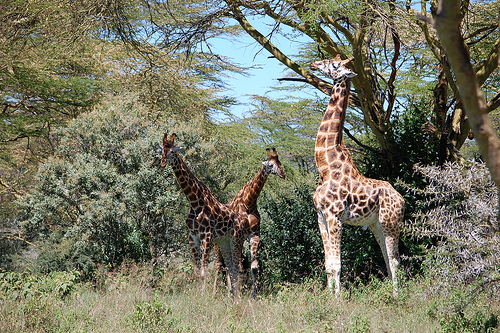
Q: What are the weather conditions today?
A: It is clear.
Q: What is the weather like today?
A: It is clear.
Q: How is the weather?
A: It is clear.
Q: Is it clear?
A: Yes, it is clear.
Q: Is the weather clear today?
A: Yes, it is clear.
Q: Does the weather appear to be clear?
A: Yes, it is clear.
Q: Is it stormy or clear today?
A: It is clear.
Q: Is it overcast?
A: No, it is clear.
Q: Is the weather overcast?
A: No, it is clear.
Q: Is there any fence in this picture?
A: No, there are no fences.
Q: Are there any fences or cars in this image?
A: No, there are no fences or cars.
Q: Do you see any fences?
A: No, there are no fences.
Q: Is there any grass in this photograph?
A: Yes, there is grass.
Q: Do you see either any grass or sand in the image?
A: Yes, there is grass.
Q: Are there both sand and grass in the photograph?
A: No, there is grass but no sand.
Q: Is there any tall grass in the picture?
A: Yes, there is tall grass.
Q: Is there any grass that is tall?
A: Yes, there is grass that is tall.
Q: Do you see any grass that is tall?
A: Yes, there is grass that is tall.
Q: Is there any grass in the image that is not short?
A: Yes, there is tall grass.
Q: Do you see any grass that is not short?
A: Yes, there is tall grass.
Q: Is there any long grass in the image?
A: Yes, there is long grass.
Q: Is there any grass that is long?
A: Yes, there is grass that is long.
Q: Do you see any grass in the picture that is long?
A: Yes, there is grass that is long.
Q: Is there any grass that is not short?
A: Yes, there is long grass.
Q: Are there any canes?
A: No, there are no canes.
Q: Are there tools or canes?
A: No, there are no canes or tools.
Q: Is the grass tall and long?
A: Yes, the grass is tall and long.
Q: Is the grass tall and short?
A: No, the grass is tall but long.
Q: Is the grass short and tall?
A: No, the grass is tall but long.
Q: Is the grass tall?
A: Yes, the grass is tall.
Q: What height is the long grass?
A: The grass is tall.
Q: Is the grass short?
A: No, the grass is tall.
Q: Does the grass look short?
A: No, the grass is tall.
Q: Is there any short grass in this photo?
A: No, there is grass but it is tall.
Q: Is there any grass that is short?
A: No, there is grass but it is tall.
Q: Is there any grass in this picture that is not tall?
A: No, there is grass but it is tall.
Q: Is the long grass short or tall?
A: The grass is tall.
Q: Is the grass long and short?
A: No, the grass is long but tall.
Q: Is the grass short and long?
A: No, the grass is long but tall.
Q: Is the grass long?
A: Yes, the grass is long.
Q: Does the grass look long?
A: Yes, the grass is long.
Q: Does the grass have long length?
A: Yes, the grass is long.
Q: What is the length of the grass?
A: The grass is long.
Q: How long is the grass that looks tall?
A: The grass is long.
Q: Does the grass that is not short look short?
A: No, the grass is long.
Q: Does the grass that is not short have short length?
A: No, the grass is long.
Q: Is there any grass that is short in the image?
A: No, there is grass but it is long.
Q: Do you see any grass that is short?
A: No, there is grass but it is long.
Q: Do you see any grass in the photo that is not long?
A: No, there is grass but it is long.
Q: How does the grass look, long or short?
A: The grass is long.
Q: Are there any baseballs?
A: No, there are no baseballs.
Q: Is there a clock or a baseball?
A: No, there are no baseballs or clocks.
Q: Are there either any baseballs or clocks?
A: No, there are no baseballs or clocks.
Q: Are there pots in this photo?
A: No, there are no pots.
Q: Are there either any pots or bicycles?
A: No, there are no pots or bicycles.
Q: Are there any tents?
A: No, there are no tents.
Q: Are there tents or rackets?
A: No, there are no tents or rackets.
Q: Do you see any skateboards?
A: No, there are no skateboards.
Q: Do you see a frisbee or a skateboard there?
A: No, there are no skateboards or frisbees.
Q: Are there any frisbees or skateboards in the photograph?
A: No, there are no skateboards or frisbees.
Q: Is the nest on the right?
A: Yes, the nest is on the right of the image.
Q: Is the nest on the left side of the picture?
A: No, the nest is on the right of the image.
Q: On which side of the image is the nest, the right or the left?
A: The nest is on the right of the image.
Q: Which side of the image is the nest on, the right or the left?
A: The nest is on the right of the image.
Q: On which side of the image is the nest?
A: The nest is on the right of the image.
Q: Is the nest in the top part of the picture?
A: Yes, the nest is in the top of the image.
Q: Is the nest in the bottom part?
A: No, the nest is in the top of the image.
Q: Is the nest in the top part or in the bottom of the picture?
A: The nest is in the top of the image.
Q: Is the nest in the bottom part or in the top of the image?
A: The nest is in the top of the image.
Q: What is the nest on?
A: The nest is on the tree.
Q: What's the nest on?
A: The nest is on the tree.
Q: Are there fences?
A: No, there are no fences.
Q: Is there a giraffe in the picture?
A: Yes, there is a giraffe.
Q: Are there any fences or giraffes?
A: Yes, there is a giraffe.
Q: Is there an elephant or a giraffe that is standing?
A: Yes, the giraffe is standing.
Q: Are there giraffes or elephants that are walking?
A: Yes, the giraffe is walking.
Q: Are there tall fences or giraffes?
A: Yes, there is a tall giraffe.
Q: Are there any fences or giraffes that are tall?
A: Yes, the giraffe is tall.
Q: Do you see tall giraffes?
A: Yes, there is a tall giraffe.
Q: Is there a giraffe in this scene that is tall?
A: Yes, there is a giraffe that is tall.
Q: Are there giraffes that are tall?
A: Yes, there is a giraffe that is tall.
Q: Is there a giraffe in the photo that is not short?
A: Yes, there is a tall giraffe.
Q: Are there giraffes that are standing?
A: Yes, there is a giraffe that is standing.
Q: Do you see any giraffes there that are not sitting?
A: Yes, there is a giraffe that is standing .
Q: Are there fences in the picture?
A: No, there are no fences.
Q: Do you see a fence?
A: No, there are no fences.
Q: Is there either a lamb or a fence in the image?
A: No, there are no fences or lambs.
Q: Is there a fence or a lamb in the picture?
A: No, there are no fences or lambs.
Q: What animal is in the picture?
A: The animal is a giraffe.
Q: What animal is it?
A: The animal is a giraffe.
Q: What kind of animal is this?
A: This is a giraffe.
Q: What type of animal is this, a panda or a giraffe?
A: This is a giraffe.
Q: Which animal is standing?
A: The animal is a giraffe.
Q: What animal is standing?
A: The animal is a giraffe.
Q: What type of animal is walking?
A: The animal is a giraffe.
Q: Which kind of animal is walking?
A: The animal is a giraffe.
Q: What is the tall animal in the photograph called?
A: The animal is a giraffe.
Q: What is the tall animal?
A: The animal is a giraffe.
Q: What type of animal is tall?
A: The animal is a giraffe.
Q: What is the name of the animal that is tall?
A: The animal is a giraffe.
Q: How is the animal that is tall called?
A: The animal is a giraffe.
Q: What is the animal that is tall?
A: The animal is a giraffe.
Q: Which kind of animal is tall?
A: The animal is a giraffe.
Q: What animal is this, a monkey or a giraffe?
A: This is a giraffe.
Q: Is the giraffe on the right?
A: Yes, the giraffe is on the right of the image.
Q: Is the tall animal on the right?
A: Yes, the giraffe is on the right of the image.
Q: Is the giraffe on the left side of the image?
A: No, the giraffe is on the right of the image.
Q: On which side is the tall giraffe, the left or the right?
A: The giraffe is on the right of the image.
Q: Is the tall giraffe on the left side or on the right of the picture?
A: The giraffe is on the right of the image.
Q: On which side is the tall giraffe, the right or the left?
A: The giraffe is on the right of the image.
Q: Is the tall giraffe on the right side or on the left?
A: The giraffe is on the right of the image.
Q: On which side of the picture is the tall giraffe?
A: The giraffe is on the right of the image.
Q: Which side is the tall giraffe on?
A: The giraffe is on the right of the image.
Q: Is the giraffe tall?
A: Yes, the giraffe is tall.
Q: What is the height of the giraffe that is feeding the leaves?
A: The giraffe is tall.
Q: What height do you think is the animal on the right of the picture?
A: The giraffe is tall.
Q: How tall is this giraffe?
A: The giraffe is tall.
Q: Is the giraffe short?
A: No, the giraffe is tall.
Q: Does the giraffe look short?
A: No, the giraffe is tall.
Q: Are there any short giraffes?
A: No, there is a giraffe but it is tall.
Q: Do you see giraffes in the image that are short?
A: No, there is a giraffe but it is tall.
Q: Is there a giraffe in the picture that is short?
A: No, there is a giraffe but it is tall.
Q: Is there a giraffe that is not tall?
A: No, there is a giraffe but it is tall.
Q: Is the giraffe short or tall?
A: The giraffe is tall.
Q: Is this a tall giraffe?
A: Yes, this is a tall giraffe.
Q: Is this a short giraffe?
A: No, this is a tall giraffe.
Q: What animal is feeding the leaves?
A: The giraffe is feeding the leaves.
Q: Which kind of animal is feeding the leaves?
A: The animal is a giraffe.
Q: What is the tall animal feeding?
A: The giraffe is feeding the leaves.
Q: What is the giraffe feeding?
A: The giraffe is feeding the leaves.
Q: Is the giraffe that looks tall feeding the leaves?
A: Yes, the giraffe is feeding the leaves.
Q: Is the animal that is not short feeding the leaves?
A: Yes, the giraffe is feeding the leaves.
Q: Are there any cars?
A: No, there are no cars.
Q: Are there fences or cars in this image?
A: No, there are no cars or fences.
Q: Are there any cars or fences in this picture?
A: No, there are no cars or fences.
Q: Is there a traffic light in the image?
A: No, there are no traffic lights.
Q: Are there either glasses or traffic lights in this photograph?
A: No, there are no traffic lights or glasses.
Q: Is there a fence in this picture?
A: No, there are no fences.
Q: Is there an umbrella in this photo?
A: No, there are no umbrellas.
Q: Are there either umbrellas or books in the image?
A: No, there are no umbrellas or books.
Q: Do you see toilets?
A: No, there are no toilets.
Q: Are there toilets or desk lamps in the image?
A: No, there are no toilets or desk lamps.